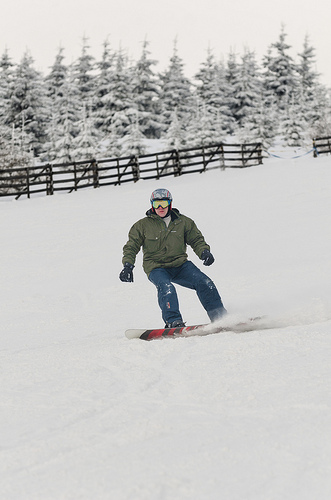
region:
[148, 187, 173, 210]
white helmet on the man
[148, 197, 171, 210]
goggles worn by the man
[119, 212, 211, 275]
green jacket on the man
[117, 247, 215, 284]
black gloves on the man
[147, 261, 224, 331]
blue jeans on the man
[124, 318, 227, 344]
white, black, and red snowboard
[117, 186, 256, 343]
man snowboarding in the snow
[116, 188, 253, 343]
snowboarder going down the hill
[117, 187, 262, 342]
man racing down the snow covered hill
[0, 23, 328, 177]
trees covered in snow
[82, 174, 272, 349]
a man riding a snowboard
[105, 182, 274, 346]
a man snowboarding down a hill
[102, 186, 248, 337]
a man looking at the camera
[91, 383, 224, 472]
white snow of the ski slope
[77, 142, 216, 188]
black wooden fence next to the ski slope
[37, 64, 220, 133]
snow covered trees next to the ski slope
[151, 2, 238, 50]
cloudy grey skies over the scene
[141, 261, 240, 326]
the man's blue snow pants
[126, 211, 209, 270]
the man's green jacket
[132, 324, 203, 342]
red, white and black base of the snowboard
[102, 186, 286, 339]
man is snowboarding in the mountain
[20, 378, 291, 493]
white and pure snow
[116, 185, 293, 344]
man snowboarding on snow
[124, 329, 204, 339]
snowboard is red and black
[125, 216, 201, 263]
man wearing a ski jacket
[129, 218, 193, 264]
man wearing a green jacket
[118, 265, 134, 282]
man wearing black gloves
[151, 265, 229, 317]
man wearing blue pants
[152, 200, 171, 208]
man wearing goggles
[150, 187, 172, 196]
man wearing a helmet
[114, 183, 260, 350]
a man snowboarding down a ski slope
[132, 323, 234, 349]
red, white and black base of the snowboard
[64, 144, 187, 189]
brown wood fence next to the ski slope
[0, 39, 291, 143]
many snow covered trees next to the ski slope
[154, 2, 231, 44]
cloudy white skies over the mountain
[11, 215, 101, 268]
fresh snow on the ground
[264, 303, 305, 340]
track marks in the snow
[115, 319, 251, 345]
snow board in the snow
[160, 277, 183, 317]
snow on blue jeans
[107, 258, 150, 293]
blue gloves on hand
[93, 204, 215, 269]
green ski jacket with hoodie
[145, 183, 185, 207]
silver and red helmet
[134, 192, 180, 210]
yellow and blue goggles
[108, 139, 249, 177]
black fence in the snow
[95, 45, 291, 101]
tall snow covered trees